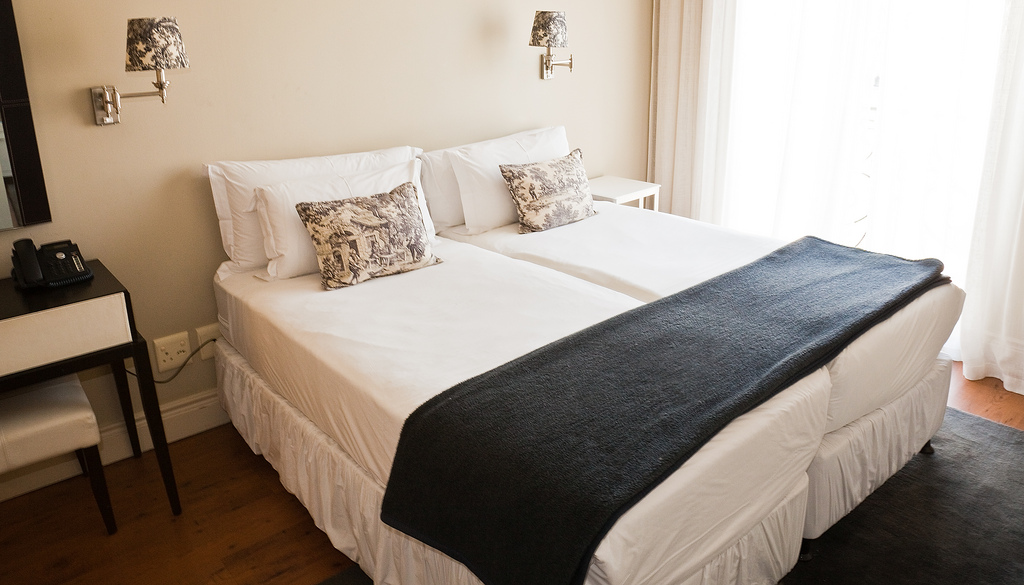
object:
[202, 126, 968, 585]
bed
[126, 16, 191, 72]
lampshade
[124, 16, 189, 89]
lamp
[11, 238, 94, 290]
telephone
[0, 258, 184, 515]
desk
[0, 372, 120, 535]
bench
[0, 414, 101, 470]
edge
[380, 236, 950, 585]
blanket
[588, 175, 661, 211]
table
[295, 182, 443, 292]
pillow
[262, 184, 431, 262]
pillow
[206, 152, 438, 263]
pillow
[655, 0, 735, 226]
curtains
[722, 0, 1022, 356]
window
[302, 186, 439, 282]
pillow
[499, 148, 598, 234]
pillow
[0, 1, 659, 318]
wall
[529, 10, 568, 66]
lamp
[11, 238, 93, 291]
phone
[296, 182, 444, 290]
design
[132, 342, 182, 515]
leg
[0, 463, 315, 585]
floor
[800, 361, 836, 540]
gap